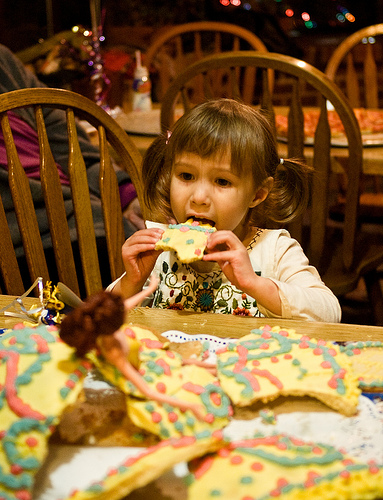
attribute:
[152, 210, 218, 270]
cookie — bell shaped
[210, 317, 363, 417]
cookie — bell shaped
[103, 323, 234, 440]
cookie — bell shaped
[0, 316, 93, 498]
cookie — bell shaped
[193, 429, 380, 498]
cookie — bell shaped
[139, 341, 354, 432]
decorations — red and green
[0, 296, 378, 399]
table — wood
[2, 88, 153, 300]
chair — wooden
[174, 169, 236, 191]
eyes — dark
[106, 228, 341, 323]
shirt — girl's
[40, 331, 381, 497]
cloth — white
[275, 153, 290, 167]
ties — white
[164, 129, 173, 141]
ties — white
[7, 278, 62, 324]
ribbons — knotted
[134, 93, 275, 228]
girl — little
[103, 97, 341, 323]
girl — little